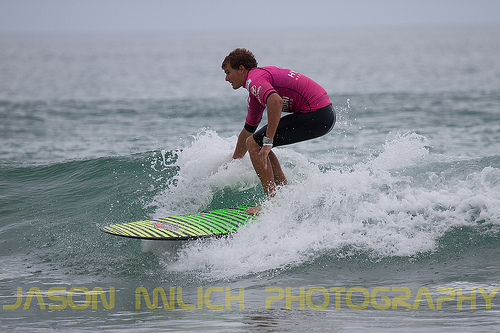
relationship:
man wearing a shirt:
[223, 48, 338, 214] [244, 66, 333, 132]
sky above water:
[1, 0, 500, 26] [2, 21, 499, 330]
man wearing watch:
[223, 48, 338, 214] [262, 136, 274, 146]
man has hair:
[223, 48, 338, 214] [222, 47, 260, 73]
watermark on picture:
[3, 286, 500, 310] [1, 1, 500, 332]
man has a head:
[223, 48, 338, 214] [223, 48, 258, 90]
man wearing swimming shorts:
[223, 48, 338, 214] [253, 103, 337, 149]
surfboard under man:
[100, 203, 262, 241] [223, 48, 338, 214]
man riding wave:
[223, 48, 338, 214] [1, 99, 500, 331]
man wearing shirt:
[223, 48, 338, 214] [244, 66, 333, 132]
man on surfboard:
[223, 48, 338, 214] [100, 203, 262, 241]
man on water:
[223, 48, 338, 214] [2, 21, 499, 330]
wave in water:
[1, 99, 500, 331] [2, 21, 499, 330]